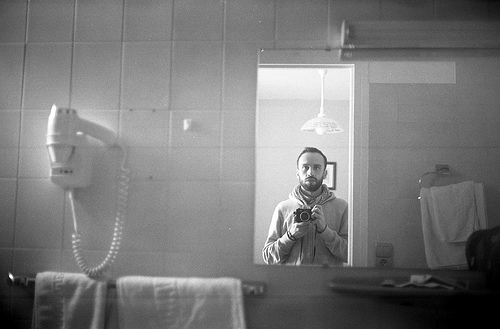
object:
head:
[295, 145, 328, 191]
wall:
[368, 46, 499, 328]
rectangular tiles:
[122, 0, 174, 42]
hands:
[308, 203, 326, 232]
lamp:
[298, 67, 343, 135]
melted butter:
[42, 102, 127, 189]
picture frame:
[321, 161, 337, 189]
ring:
[326, 273, 499, 298]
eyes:
[313, 165, 320, 170]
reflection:
[254, 146, 348, 266]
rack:
[5, 269, 265, 298]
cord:
[65, 140, 130, 278]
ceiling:
[257, 67, 352, 101]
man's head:
[295, 145, 329, 188]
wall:
[136, 0, 213, 254]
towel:
[30, 270, 109, 328]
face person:
[261, 146, 349, 266]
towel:
[107, 274, 245, 328]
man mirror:
[255, 65, 350, 266]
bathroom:
[0, 0, 499, 328]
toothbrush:
[378, 278, 453, 289]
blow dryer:
[45, 102, 117, 190]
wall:
[2, 7, 250, 275]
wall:
[256, 98, 348, 147]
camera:
[291, 208, 317, 223]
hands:
[287, 215, 311, 240]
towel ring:
[415, 163, 459, 201]